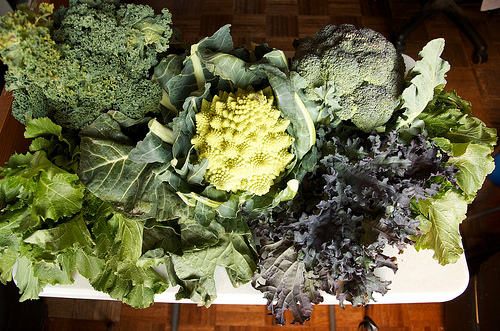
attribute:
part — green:
[109, 74, 145, 106]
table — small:
[2, 15, 489, 300]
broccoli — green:
[27, 8, 184, 123]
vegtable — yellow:
[161, 46, 295, 208]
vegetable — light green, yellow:
[9, 145, 155, 306]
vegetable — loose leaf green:
[255, 135, 472, 302]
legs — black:
[388, 12, 498, 71]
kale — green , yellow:
[2, 9, 169, 125]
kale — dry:
[2, 0, 86, 123]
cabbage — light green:
[192, 83, 300, 207]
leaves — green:
[134, 25, 328, 259]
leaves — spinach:
[0, 114, 195, 328]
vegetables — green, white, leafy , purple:
[2, 10, 497, 318]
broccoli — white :
[126, 2, 347, 322]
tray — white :
[18, 181, 479, 319]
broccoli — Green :
[292, 10, 412, 140]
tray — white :
[11, 213, 479, 307]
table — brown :
[2, 0, 497, 330]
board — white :
[25, 183, 485, 317]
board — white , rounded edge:
[14, 147, 485, 296]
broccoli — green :
[311, 18, 416, 137]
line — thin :
[35, 171, 75, 211]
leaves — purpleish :
[255, 123, 460, 322]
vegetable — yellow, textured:
[189, 89, 293, 192]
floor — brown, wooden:
[0, 2, 497, 328]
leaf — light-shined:
[399, 31, 450, 118]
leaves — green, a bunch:
[6, 143, 162, 319]